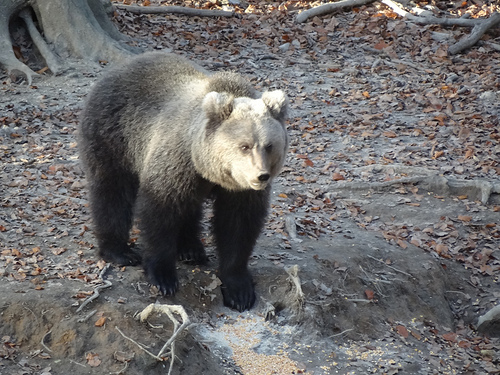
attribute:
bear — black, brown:
[75, 51, 298, 310]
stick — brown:
[137, 304, 192, 373]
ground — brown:
[1, 296, 216, 370]